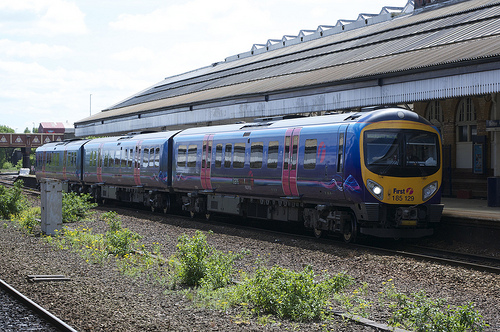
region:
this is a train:
[28, 92, 462, 236]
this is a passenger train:
[6, 94, 448, 231]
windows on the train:
[35, 130, 360, 190]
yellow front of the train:
[336, 104, 458, 233]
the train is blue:
[17, 102, 410, 216]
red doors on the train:
[258, 116, 305, 201]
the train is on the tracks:
[35, 68, 496, 323]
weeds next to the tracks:
[18, 188, 363, 327]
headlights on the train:
[360, 171, 447, 212]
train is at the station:
[8, 13, 498, 268]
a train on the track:
[197, 74, 493, 299]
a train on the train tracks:
[233, 49, 487, 294]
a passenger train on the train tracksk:
[189, 56, 422, 325]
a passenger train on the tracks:
[210, 74, 492, 324]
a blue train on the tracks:
[237, 91, 497, 313]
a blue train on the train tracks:
[266, 81, 498, 287]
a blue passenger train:
[209, 53, 499, 265]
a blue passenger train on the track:
[139, 60, 496, 295]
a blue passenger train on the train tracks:
[194, 67, 494, 270]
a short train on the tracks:
[17, 81, 487, 284]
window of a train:
[361, 118, 407, 175]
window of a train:
[403, 130, 439, 170]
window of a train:
[305, 130, 325, 168]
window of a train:
[280, 135, 305, 168]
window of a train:
[264, 130, 296, 169]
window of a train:
[243, 133, 274, 174]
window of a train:
[217, 135, 236, 165]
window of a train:
[198, 140, 214, 167]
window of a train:
[170, 138, 197, 175]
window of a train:
[130, 140, 165, 189]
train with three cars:
[33, 110, 445, 219]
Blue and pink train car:
[175, 123, 372, 203]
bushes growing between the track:
[103, 230, 361, 317]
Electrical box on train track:
[30, 175, 74, 232]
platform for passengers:
[455, 181, 487, 224]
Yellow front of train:
[346, 109, 445, 216]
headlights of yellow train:
[363, 170, 456, 206]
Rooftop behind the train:
[35, 119, 70, 132]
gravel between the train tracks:
[93, 274, 188, 319]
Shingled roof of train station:
[289, 48, 440, 62]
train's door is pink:
[274, 121, 307, 205]